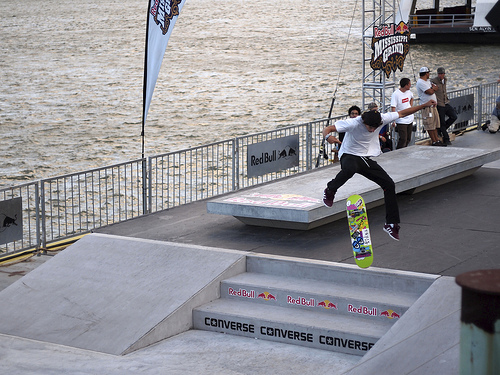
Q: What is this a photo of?
A: A man skateboarding.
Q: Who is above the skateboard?
A: The skateboarder.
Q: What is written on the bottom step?
A: Converse.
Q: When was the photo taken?
A: Daytime.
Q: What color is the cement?
A: Grey.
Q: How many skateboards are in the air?
A: One.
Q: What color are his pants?
A: Black.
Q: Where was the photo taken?
A: At a skatepark.